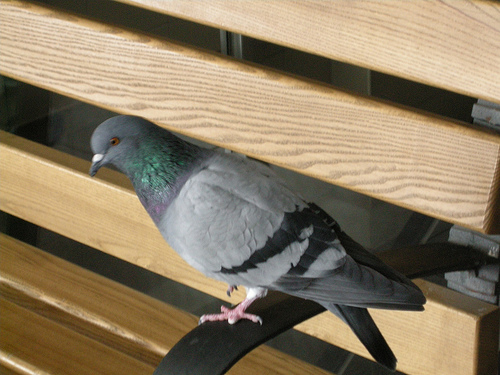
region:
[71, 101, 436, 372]
Dove stand on a bench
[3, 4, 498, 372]
Bench is brown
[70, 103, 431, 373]
Dove face to the left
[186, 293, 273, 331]
Left leg of dove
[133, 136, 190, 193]
Neck of dove is green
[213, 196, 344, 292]
Part of wings are black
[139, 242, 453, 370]
Armrest of bench is black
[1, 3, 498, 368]
Bench is made of wood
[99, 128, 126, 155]
Eye of dove is brown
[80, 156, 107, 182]
Dove peak is gray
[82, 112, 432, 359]
pigeon standing on bench rail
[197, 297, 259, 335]
pink bird foot on black metal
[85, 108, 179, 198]
pigeon head bent forward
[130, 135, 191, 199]
green tint on neck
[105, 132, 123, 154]
brown bird eye with black pupil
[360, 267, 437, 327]
gray feathers on tail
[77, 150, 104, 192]
beak on pigeon face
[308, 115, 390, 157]
wood grain on bench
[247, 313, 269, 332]
toenail on bird foot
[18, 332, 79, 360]
seat of wood bench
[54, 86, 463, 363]
bird is light and dark grey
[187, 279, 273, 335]
Small foot of a pigeon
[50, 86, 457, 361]
Pigeon sitting on a chair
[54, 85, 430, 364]
Bird sitting on a chair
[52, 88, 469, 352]
Grey and black bird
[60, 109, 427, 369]
Grey and black bird on a bench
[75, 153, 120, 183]
Small black beak of a bird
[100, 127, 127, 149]
Small orange pigeon eye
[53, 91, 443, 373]
Bird with black stripes on wings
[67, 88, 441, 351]
Bird with grey breast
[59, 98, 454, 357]
Bird on a bench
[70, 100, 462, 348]
A pigeon is on a bench.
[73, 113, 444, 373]
The pigeon is on the armrest.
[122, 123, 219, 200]
The pigeon's feathers are green.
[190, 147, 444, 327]
The pigeon's feathers are gray and black.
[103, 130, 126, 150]
The pigeon's eye is orange.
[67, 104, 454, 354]
The pigeon is facing left.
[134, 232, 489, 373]
The bench armrest is black.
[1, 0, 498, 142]
The bench is made of wood.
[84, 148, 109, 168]
A white spot is on the pigeon's beak.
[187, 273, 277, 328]
The pigeon's feet grip the armrest.